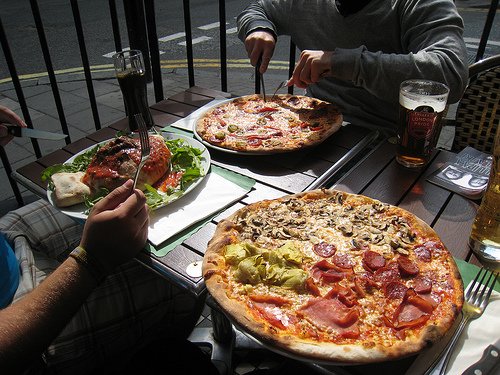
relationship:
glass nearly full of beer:
[395, 78, 450, 170] [396, 99, 447, 164]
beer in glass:
[396, 99, 447, 164] [395, 78, 450, 170]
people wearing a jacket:
[229, 0, 470, 130] [237, 0, 468, 131]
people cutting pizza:
[229, 0, 470, 130] [196, 92, 345, 156]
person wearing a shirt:
[2, 105, 194, 375] [0, 235, 21, 309]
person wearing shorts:
[2, 105, 194, 375] [1, 200, 198, 375]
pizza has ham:
[203, 189, 466, 365] [250, 261, 432, 342]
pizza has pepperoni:
[203, 189, 466, 365] [312, 239, 432, 302]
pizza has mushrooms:
[203, 189, 466, 365] [240, 192, 411, 249]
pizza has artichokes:
[203, 189, 466, 365] [223, 241, 306, 291]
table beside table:
[9, 83, 380, 298] [203, 137, 499, 374]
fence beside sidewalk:
[0, 0, 499, 206] [2, 74, 202, 214]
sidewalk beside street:
[2, 74, 202, 214] [2, 0, 499, 88]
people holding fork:
[229, 0, 470, 130] [271, 70, 332, 106]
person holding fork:
[2, 105, 194, 375] [129, 111, 151, 198]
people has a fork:
[229, 0, 470, 130] [271, 70, 332, 106]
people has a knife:
[229, 0, 470, 130] [256, 58, 267, 101]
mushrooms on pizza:
[240, 192, 411, 249] [203, 189, 466, 365]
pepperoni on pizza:
[312, 239, 432, 302] [203, 189, 466, 365]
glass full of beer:
[395, 78, 450, 170] [396, 99, 447, 164]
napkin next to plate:
[148, 171, 252, 247] [46, 131, 212, 222]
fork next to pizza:
[421, 266, 498, 373] [203, 189, 466, 365]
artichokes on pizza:
[223, 241, 306, 291] [203, 189, 466, 365]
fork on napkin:
[421, 266, 498, 373] [404, 277, 499, 373]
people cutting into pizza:
[229, 0, 470, 130] [196, 92, 345, 156]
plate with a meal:
[46, 131, 212, 222] [52, 132, 172, 210]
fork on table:
[421, 266, 498, 373] [203, 137, 499, 374]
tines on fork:
[271, 81, 284, 103] [271, 70, 332, 106]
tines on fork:
[131, 111, 150, 152] [129, 111, 151, 198]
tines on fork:
[465, 266, 499, 303] [421, 266, 498, 373]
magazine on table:
[425, 145, 496, 202] [203, 137, 499, 374]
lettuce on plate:
[37, 137, 207, 209] [46, 131, 212, 222]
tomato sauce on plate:
[85, 136, 184, 196] [46, 131, 212, 222]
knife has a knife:
[256, 58, 267, 101] [256, 58, 267, 101]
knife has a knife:
[3, 125, 69, 140] [3, 125, 69, 140]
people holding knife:
[229, 0, 470, 130] [256, 58, 267, 101]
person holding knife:
[2, 105, 194, 375] [3, 125, 69, 140]